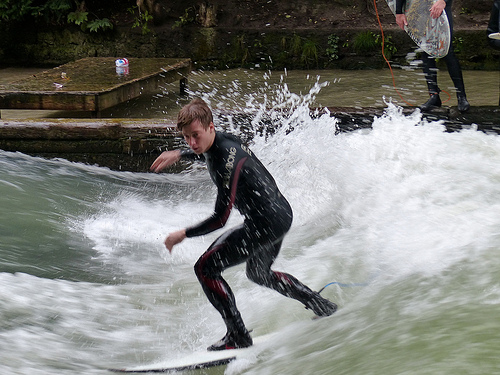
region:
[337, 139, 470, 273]
The waves are white.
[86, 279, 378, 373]
The surfboard is white.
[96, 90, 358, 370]
The person is wearing a wetsuit.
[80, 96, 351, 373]
The wetsuit is black.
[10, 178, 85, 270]
The water is green.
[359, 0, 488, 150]
A person is in the background.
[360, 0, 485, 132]
The person is carrying a surfboard.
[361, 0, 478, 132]
The surfboard is white.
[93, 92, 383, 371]
The person is on a surfboard.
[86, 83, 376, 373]
The person is wet.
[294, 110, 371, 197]
part of a splash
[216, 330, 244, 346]
edge of a shoe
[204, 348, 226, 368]
edge of a board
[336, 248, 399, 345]
part of a splash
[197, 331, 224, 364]
part of a board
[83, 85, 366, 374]
Young man surfing on a wave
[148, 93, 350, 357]
Man wearing a black and red wetsuit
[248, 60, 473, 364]
Large foamy wave hitting a wall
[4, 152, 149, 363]
Turbulent green-looking water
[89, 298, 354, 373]
White surf board with black rim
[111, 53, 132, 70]
Plastic water bottle discarded on ground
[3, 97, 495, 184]
Mossy stone wall around water's edge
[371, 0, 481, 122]
Man holding a surf board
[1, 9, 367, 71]
Plants and weeds growing on stone wall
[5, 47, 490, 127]
Channel with brown water in it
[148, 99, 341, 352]
this is a man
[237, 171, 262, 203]
the swimsuit is black in color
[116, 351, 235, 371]
this is a surfboard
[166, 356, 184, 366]
the surfboard is white in color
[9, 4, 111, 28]
this is a tree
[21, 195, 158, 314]
this is the water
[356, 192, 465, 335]
this is a wave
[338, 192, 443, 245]
the wave is white in color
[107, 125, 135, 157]
this is a pavement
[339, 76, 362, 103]
the pavement is made of stone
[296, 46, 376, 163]
part of a splash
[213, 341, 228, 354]
edge of a shoe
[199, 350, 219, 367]
edge of a board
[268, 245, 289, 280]
part of a costume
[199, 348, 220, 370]
part of a board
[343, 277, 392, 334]
part of a splash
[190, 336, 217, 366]
part of a board